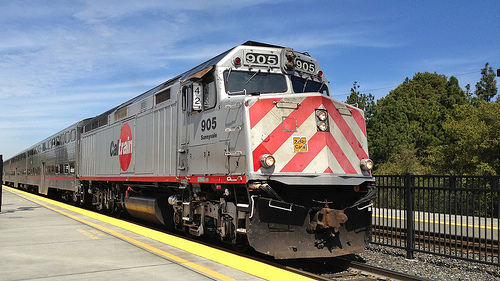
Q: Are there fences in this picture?
A: Yes, there is a fence.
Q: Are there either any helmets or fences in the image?
A: Yes, there is a fence.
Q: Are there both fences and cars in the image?
A: Yes, there are both a fence and a car.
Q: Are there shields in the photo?
A: No, there are no shields.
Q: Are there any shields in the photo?
A: No, there are no shields.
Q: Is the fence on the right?
A: Yes, the fence is on the right of the image.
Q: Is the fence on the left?
A: No, the fence is on the right of the image.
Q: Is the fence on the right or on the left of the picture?
A: The fence is on the right of the image.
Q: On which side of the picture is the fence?
A: The fence is on the right of the image.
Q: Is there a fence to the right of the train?
A: Yes, there is a fence to the right of the train.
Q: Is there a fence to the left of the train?
A: No, the fence is to the right of the train.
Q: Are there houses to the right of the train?
A: No, there is a fence to the right of the train.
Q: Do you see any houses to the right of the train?
A: No, there is a fence to the right of the train.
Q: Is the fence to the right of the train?
A: Yes, the fence is to the right of the train.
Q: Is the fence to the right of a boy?
A: No, the fence is to the right of the train.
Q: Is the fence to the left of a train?
A: No, the fence is to the right of a train.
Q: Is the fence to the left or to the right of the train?
A: The fence is to the right of the train.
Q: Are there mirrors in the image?
A: Yes, there is a mirror.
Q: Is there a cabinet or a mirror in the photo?
A: Yes, there is a mirror.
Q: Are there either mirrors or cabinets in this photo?
A: Yes, there is a mirror.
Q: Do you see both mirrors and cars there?
A: Yes, there are both a mirror and a car.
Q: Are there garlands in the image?
A: No, there are no garlands.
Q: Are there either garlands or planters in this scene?
A: No, there are no garlands or planters.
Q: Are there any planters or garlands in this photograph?
A: No, there are no garlands or planters.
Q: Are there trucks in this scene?
A: No, there are no trucks.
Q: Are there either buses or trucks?
A: No, there are no trucks or buses.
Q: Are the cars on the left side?
A: Yes, the cars are on the left of the image.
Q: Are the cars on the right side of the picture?
A: No, the cars are on the left of the image.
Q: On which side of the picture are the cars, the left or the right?
A: The cars are on the left of the image.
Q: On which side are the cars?
A: The cars are on the left of the image.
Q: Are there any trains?
A: Yes, there is a train.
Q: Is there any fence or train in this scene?
A: Yes, there is a train.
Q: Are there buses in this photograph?
A: No, there are no buses.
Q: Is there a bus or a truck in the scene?
A: No, there are no buses or trucks.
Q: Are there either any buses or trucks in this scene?
A: No, there are no buses or trucks.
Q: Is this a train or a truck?
A: This is a train.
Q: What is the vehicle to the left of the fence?
A: The vehicle is a train.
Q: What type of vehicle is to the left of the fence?
A: The vehicle is a train.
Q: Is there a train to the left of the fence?
A: Yes, there is a train to the left of the fence.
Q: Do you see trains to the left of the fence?
A: Yes, there is a train to the left of the fence.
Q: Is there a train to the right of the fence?
A: No, the train is to the left of the fence.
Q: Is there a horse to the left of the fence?
A: No, there is a train to the left of the fence.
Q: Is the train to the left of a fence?
A: Yes, the train is to the left of a fence.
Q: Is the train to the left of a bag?
A: No, the train is to the left of a fence.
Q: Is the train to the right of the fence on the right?
A: No, the train is to the left of the fence.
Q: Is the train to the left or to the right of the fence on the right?
A: The train is to the left of the fence.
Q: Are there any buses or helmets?
A: No, there are no buses or helmets.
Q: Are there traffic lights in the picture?
A: No, there are no traffic lights.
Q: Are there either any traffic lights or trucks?
A: No, there are no traffic lights or trucks.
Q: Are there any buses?
A: No, there are no buses.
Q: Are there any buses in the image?
A: No, there are no buses.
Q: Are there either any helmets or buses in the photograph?
A: No, there are no buses or helmets.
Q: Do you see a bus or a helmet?
A: No, there are no buses or helmets.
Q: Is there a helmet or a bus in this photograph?
A: No, there are no buses or helmets.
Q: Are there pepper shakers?
A: No, there are no pepper shakers.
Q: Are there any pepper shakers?
A: No, there are no pepper shakers.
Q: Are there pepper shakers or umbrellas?
A: No, there are no pepper shakers or umbrellas.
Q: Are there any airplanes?
A: No, there are no airplanes.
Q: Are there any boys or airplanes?
A: No, there are no airplanes or boys.